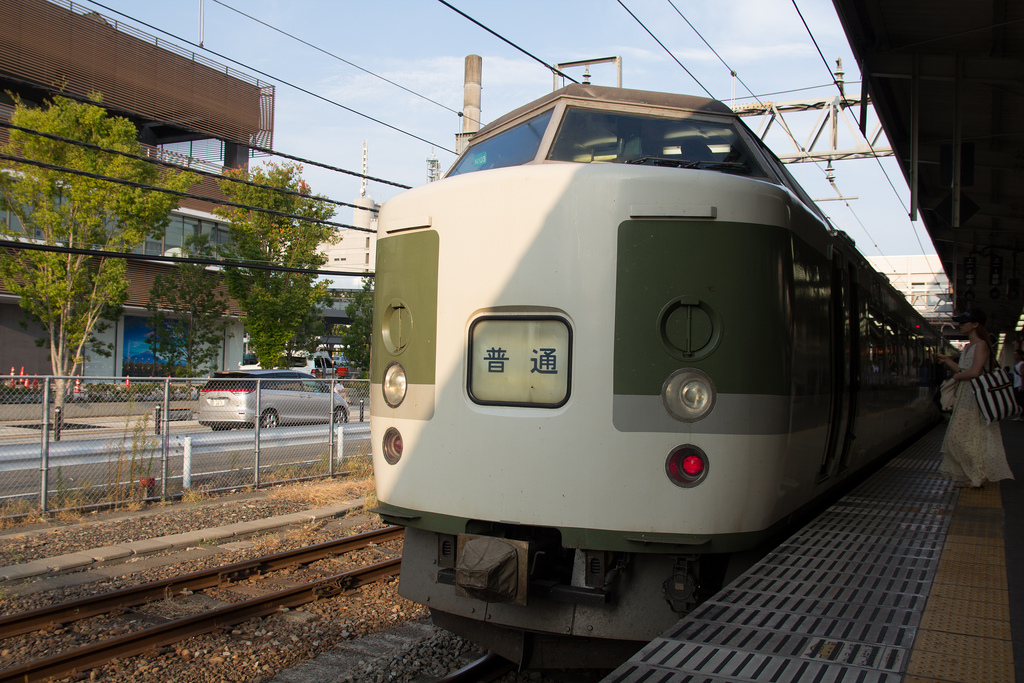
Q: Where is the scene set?
A: Train station.